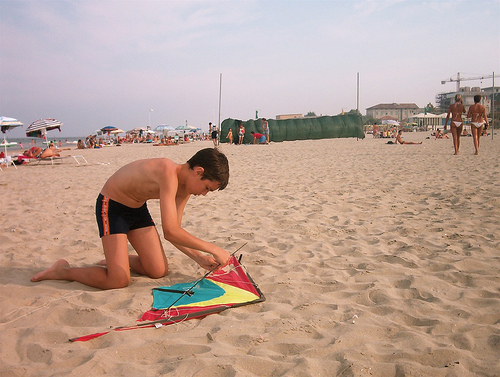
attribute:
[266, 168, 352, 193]
beach — sandy, busy, beautiful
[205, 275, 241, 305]
kite — yellow, broken, red, green, blue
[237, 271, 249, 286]
kite — red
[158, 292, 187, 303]
kite — blue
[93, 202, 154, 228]
shorts — blue, tight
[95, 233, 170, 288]
boy — kneeling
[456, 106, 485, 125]
swimsuits — white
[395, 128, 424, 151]
man — dressed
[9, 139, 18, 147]
boat — white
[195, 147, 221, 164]
hair — brown, white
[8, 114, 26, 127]
umbrella — white, gray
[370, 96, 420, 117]
building — tan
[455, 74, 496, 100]
building — large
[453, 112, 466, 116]
bikini — white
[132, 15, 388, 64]
sky — clear, blue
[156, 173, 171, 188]
skin — light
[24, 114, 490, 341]
place — sandy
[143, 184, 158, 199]
chest — bare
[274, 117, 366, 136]
tent — green